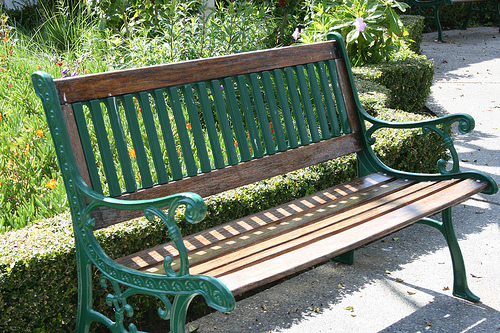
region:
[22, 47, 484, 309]
green empty wooden bench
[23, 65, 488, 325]
green empty wooden bench near flowers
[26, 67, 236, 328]
green armrest of brown wooden bench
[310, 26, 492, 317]
green armrest of brown wooden bench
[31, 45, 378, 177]
brown wooden back of bench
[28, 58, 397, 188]
brown wooden back of bench with green metal slats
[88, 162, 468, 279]
brown wooden seat of bench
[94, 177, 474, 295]
brown wooden seat of empty bench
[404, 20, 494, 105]
gray pavement in park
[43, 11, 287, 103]
green bushes near multicolored flowers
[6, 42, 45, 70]
Grass is green color.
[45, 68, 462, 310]
One bench is seen.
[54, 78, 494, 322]
Bench is brown and green color.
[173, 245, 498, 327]
Shadow falls on ground.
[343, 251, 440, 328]
Road is grey color.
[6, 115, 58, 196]
Flowers are yellow color.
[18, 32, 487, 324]
Day time picture.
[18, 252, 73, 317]
Bush is green color.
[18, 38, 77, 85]
Sunlight reflection on grass.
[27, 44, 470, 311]
No body is seen in picture.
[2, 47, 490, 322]
the bench is brown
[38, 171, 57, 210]
the flower is orange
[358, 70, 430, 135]
the bush is green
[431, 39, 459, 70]
the floor is gray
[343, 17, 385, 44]
the flower is green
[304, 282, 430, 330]
the shadow is on the ground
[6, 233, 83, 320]
the bush is manicured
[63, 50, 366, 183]
the food is made of wood and metal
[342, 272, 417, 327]
dry leaves on the ground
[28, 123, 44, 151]
yellow flowers growing in a park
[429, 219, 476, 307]
green metal legs supporting the bench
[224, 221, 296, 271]
brown wooden slats in the bench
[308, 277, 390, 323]
dried leaves scattered under the bench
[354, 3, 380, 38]
a pretty lavender flower blooming on a bush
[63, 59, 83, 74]
purple flowers growing behind the bench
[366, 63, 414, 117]
low growing green shrubs along a path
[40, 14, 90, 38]
tall spiky grass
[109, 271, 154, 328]
decorative iron work on the bench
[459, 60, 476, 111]
a paved path in a park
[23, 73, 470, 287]
the bench is wooden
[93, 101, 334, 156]
the bars are blue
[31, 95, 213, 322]
the railing is blue in color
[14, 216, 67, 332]
the bush is green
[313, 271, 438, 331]
there is reflection on the ground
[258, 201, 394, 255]
the wood is brown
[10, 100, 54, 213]
the grass is green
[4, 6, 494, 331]
the photo was taken during the day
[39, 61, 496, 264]
there is no one sitting on the bench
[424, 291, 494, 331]
there is black shadow on the floor